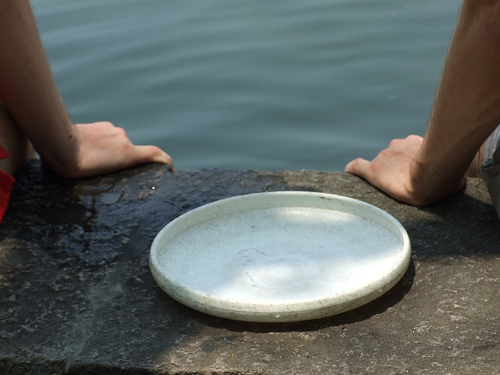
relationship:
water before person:
[27, 0, 466, 175] [347, 0, 498, 214]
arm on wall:
[409, 2, 499, 203] [0, 160, 500, 374]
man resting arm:
[2, 0, 175, 224] [3, 2, 78, 175]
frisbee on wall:
[149, 188, 413, 325] [0, 160, 500, 374]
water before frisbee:
[27, 0, 466, 175] [149, 188, 413, 325]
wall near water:
[0, 160, 500, 374] [27, 0, 466, 175]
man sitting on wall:
[2, 0, 175, 224] [0, 160, 500, 374]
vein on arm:
[474, 95, 499, 125] [409, 2, 499, 203]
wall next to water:
[0, 160, 500, 374] [27, 0, 466, 175]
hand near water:
[345, 133, 468, 206] [27, 0, 466, 175]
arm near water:
[409, 2, 499, 203] [27, 0, 466, 175]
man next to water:
[2, 0, 175, 224] [27, 0, 466, 175]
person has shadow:
[347, 0, 498, 214] [397, 195, 499, 269]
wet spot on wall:
[4, 156, 322, 268] [0, 160, 500, 374]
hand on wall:
[41, 118, 172, 175] [0, 160, 500, 374]